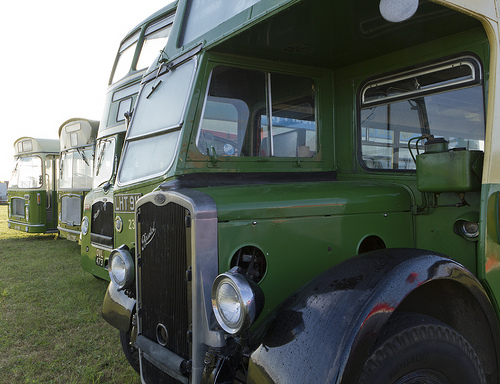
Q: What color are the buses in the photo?
A: Green.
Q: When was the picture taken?
A: Daytime.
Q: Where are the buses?
A: Parked on the ground.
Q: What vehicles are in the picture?
A: Trucks and buses.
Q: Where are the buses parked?
A: On the ground.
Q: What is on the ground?
A: Grass.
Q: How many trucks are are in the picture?
A: One.